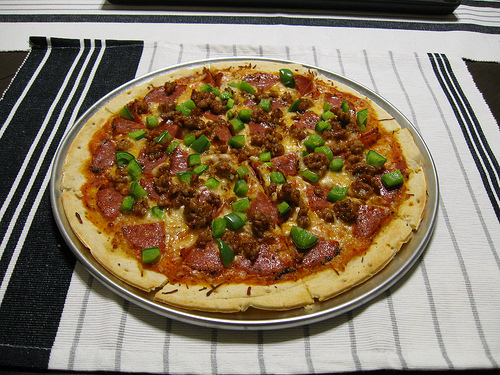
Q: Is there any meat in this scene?
A: Yes, there is meat.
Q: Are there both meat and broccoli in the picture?
A: No, there is meat but no broccoli.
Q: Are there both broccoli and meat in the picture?
A: No, there is meat but no broccoli.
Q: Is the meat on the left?
A: Yes, the meat is on the left of the image.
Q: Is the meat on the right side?
A: No, the meat is on the left of the image.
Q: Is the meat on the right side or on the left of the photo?
A: The meat is on the left of the image.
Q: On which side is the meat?
A: The meat is on the left of the image.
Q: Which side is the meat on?
A: The meat is on the left of the image.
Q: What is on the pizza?
A: The meat is on the pizza.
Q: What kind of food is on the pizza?
A: The food is meat.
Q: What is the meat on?
A: The meat is on the pizza.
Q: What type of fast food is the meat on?
A: The meat is on the pizza.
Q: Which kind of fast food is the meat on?
A: The meat is on the pizza.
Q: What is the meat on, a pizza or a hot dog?
A: The meat is on a pizza.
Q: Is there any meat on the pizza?
A: Yes, there is meat on the pizza.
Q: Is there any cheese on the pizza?
A: No, there is meat on the pizza.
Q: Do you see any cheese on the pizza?
A: No, there is meat on the pizza.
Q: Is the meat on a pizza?
A: Yes, the meat is on a pizza.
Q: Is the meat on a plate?
A: No, the meat is on a pizza.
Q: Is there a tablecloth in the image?
A: Yes, there is a tablecloth.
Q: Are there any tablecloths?
A: Yes, there is a tablecloth.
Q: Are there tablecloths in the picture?
A: Yes, there is a tablecloth.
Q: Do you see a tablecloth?
A: Yes, there is a tablecloth.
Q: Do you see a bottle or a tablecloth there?
A: Yes, there is a tablecloth.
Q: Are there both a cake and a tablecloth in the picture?
A: No, there is a tablecloth but no cakes.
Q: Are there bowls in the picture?
A: No, there are no bowls.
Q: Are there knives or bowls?
A: No, there are no bowls or knives.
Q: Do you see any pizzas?
A: Yes, there is a pizza.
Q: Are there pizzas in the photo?
A: Yes, there is a pizza.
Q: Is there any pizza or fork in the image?
A: Yes, there is a pizza.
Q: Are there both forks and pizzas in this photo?
A: No, there is a pizza but no forks.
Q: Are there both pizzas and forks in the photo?
A: No, there is a pizza but no forks.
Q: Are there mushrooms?
A: No, there are no mushrooms.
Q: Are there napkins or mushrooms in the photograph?
A: No, there are no mushrooms or napkins.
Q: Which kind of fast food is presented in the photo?
A: The fast food is a pizza.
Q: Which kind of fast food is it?
A: The food is a pizza.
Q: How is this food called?
A: This is a pizza.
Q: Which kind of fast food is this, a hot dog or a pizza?
A: This is a pizza.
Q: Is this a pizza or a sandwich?
A: This is a pizza.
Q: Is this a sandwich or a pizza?
A: This is a pizza.